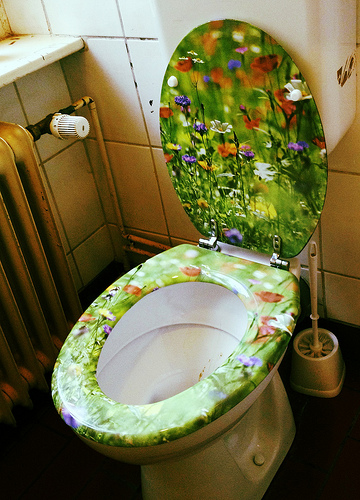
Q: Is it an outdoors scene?
A: Yes, it is outdoors.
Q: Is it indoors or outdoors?
A: It is outdoors.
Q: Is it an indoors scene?
A: No, it is outdoors.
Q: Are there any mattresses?
A: No, there are no mattresses.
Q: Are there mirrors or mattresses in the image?
A: No, there are no mattresses or mirrors.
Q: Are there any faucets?
A: No, there are no faucets.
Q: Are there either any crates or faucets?
A: No, there are no faucets or crates.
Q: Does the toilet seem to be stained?
A: Yes, the toilet is stained.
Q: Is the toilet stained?
A: Yes, the toilet is stained.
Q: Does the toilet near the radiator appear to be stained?
A: Yes, the toilet is stained.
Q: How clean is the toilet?
A: The toilet is stained.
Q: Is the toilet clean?
A: No, the toilet is stained.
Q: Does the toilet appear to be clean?
A: No, the toilet is stained.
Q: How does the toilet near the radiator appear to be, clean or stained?
A: The toilet is stained.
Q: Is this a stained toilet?
A: Yes, this is a stained toilet.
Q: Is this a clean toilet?
A: No, this is a stained toilet.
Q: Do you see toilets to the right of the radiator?
A: Yes, there is a toilet to the right of the radiator.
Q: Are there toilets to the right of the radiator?
A: Yes, there is a toilet to the right of the radiator.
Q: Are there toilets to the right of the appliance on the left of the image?
A: Yes, there is a toilet to the right of the radiator.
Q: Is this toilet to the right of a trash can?
A: No, the toilet is to the right of the radiator.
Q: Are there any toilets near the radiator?
A: Yes, there is a toilet near the radiator.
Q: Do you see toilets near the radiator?
A: Yes, there is a toilet near the radiator.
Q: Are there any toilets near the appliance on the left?
A: Yes, there is a toilet near the radiator.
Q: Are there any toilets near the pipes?
A: Yes, there is a toilet near the pipes.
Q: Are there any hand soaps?
A: No, there are no hand soaps.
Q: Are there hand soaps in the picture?
A: No, there are no hand soaps.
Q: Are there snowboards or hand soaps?
A: No, there are no hand soaps or snowboards.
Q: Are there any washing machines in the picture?
A: No, there are no washing machines.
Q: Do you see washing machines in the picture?
A: No, there are no washing machines.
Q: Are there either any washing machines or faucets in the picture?
A: No, there are no washing machines or faucets.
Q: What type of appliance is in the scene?
A: The appliance is a radiator.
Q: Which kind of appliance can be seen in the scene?
A: The appliance is a radiator.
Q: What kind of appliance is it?
A: The appliance is a radiator.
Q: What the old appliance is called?
A: The appliance is a radiator.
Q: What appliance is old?
A: The appliance is a radiator.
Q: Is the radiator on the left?
A: Yes, the radiator is on the left of the image.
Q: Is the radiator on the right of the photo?
A: No, the radiator is on the left of the image.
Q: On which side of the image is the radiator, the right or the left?
A: The radiator is on the left of the image.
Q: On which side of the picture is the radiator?
A: The radiator is on the left of the image.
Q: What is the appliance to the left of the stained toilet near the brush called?
A: The appliance is a radiator.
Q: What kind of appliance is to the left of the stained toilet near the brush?
A: The appliance is a radiator.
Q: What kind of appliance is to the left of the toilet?
A: The appliance is a radiator.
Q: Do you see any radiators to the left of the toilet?
A: Yes, there is a radiator to the left of the toilet.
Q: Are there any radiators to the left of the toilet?
A: Yes, there is a radiator to the left of the toilet.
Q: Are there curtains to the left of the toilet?
A: No, there is a radiator to the left of the toilet.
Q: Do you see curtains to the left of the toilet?
A: No, there is a radiator to the left of the toilet.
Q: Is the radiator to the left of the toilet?
A: Yes, the radiator is to the left of the toilet.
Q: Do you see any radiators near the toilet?
A: Yes, there is a radiator near the toilet.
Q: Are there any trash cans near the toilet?
A: No, there is a radiator near the toilet.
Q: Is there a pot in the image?
A: No, there are no pots.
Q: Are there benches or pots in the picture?
A: No, there are no pots or benches.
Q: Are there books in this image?
A: No, there are no books.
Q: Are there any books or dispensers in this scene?
A: No, there are no books or dispensers.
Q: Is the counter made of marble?
A: No, the counter is made of steel.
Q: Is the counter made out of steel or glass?
A: The counter is made of steel.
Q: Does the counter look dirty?
A: Yes, the counter is dirty.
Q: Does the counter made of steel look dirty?
A: Yes, the counter is dirty.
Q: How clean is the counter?
A: The counter is dirty.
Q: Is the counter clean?
A: No, the counter is dirty.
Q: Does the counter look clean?
A: No, the counter is dirty.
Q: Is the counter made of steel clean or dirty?
A: The counter is dirty.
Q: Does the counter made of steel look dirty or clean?
A: The counter is dirty.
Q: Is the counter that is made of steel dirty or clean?
A: The counter is dirty.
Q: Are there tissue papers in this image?
A: No, there are no tissue papers.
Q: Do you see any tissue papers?
A: No, there are no tissue papers.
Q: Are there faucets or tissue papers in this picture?
A: No, there are no tissue papers or faucets.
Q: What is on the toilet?
A: The flowers are on the toilet.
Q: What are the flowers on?
A: The flowers are on the toilet.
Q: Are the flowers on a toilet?
A: Yes, the flowers are on a toilet.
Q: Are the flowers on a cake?
A: No, the flowers are on a toilet.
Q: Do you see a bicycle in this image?
A: No, there are no bicycles.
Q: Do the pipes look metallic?
A: Yes, the pipes are metallic.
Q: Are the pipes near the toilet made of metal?
A: Yes, the pipes are made of metal.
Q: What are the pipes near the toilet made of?
A: The pipes are made of metal.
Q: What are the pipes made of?
A: The pipes are made of metal.